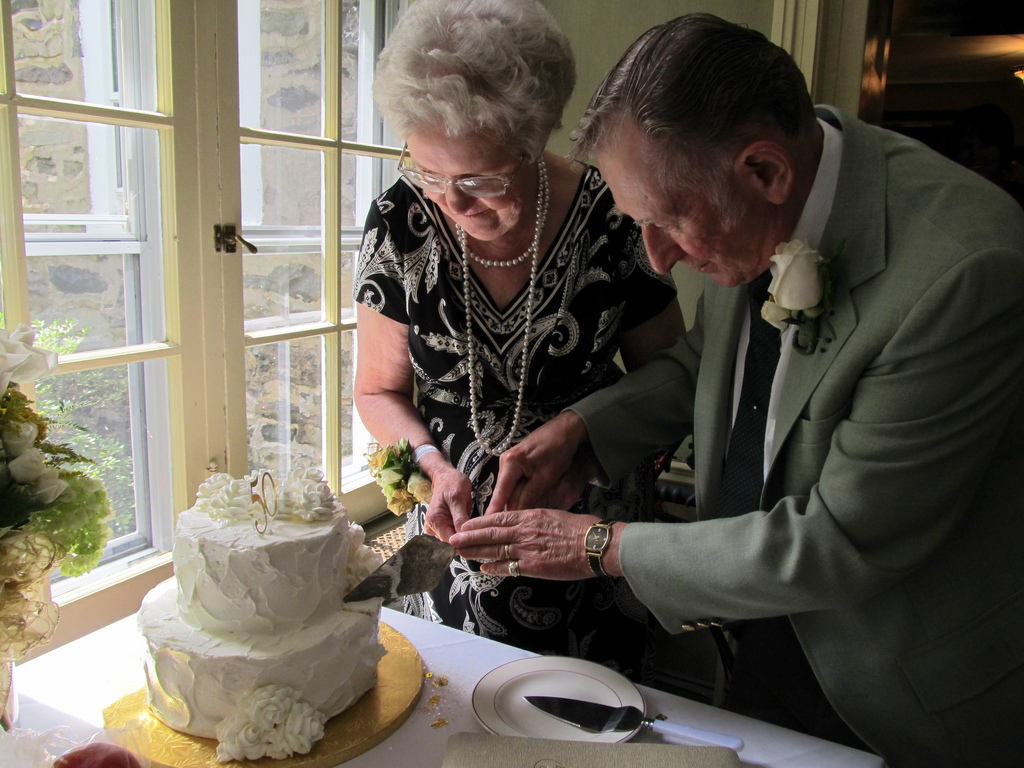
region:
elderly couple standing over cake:
[137, 1, 1013, 739]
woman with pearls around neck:
[349, 4, 683, 643]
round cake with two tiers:
[139, 484, 381, 740]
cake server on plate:
[469, 652, 741, 757]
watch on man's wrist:
[453, 504, 621, 580]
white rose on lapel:
[762, 104, 887, 478]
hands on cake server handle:
[355, 429, 594, 604]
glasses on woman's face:
[400, 125, 524, 247]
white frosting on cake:
[143, 505, 377, 746]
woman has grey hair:
[359, 15, 595, 170]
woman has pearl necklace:
[430, 170, 579, 483]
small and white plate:
[500, 649, 643, 763]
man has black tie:
[705, 255, 819, 494]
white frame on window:
[14, 32, 414, 549]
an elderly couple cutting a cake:
[262, 4, 854, 672]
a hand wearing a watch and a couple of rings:
[449, 499, 637, 601]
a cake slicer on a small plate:
[468, 641, 724, 753]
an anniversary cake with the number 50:
[114, 459, 434, 766]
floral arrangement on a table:
[0, 335, 114, 734]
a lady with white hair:
[353, 4, 572, 261]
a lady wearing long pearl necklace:
[357, 9, 580, 478]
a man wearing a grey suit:
[585, 9, 1022, 722]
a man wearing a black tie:
[580, 9, 814, 635]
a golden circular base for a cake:
[91, 581, 442, 750]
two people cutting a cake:
[338, 0, 1022, 767]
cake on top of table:
[111, 465, 424, 763]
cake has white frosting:
[106, 462, 430, 766]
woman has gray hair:
[351, 0, 685, 669]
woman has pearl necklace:
[350, 0, 702, 671]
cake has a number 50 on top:
[101, 461, 434, 766]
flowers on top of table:
[3, 310, 120, 734]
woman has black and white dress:
[351, 0, 694, 653]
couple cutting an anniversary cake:
[57, 28, 974, 746]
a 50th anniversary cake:
[117, 420, 449, 737]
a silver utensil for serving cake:
[469, 670, 765, 766]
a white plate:
[437, 619, 646, 753]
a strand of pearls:
[419, 139, 569, 516]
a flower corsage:
[323, 408, 489, 530]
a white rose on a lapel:
[748, 224, 859, 371]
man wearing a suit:
[495, 34, 998, 543]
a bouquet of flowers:
[0, 328, 128, 686]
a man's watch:
[579, 511, 614, 576]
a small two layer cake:
[147, 455, 397, 734]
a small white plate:
[472, 654, 650, 752]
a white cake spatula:
[519, 689, 751, 748]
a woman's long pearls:
[437, 154, 559, 449]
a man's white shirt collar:
[795, 111, 852, 252]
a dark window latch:
[204, 223, 259, 259]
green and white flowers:
[0, 359, 109, 691]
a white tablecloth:
[2, 598, 900, 764]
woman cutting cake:
[341, 10, 711, 684]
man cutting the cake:
[316, 13, 1022, 722]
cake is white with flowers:
[138, 454, 436, 758]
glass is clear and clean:
[240, 138, 329, 331]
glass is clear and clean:
[251, 329, 318, 504]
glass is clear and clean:
[336, 320, 394, 491]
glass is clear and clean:
[11, 92, 174, 358]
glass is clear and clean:
[5, 0, 177, 117]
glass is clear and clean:
[332, 2, 406, 158]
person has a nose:
[640, 217, 676, 279]